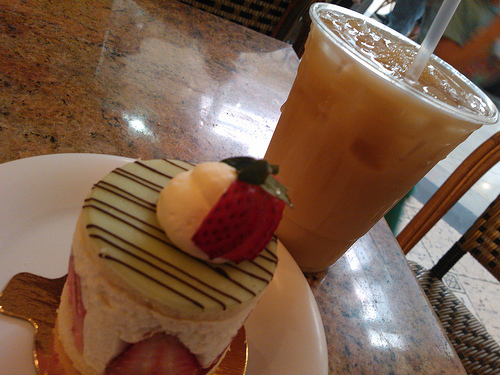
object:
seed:
[209, 226, 217, 237]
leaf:
[260, 171, 294, 208]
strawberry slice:
[194, 178, 279, 262]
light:
[199, 94, 276, 159]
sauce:
[68, 244, 86, 353]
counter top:
[0, 0, 462, 375]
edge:
[306, 2, 499, 130]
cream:
[153, 159, 234, 261]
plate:
[0, 150, 327, 374]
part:
[157, 294, 197, 331]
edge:
[155, 303, 204, 324]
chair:
[395, 132, 499, 375]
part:
[426, 245, 466, 299]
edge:
[400, 272, 432, 331]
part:
[427, 230, 447, 260]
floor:
[382, 100, 500, 346]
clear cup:
[245, 3, 499, 272]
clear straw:
[395, 0, 463, 78]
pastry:
[51, 144, 286, 371]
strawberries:
[194, 157, 294, 265]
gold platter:
[0, 270, 246, 374]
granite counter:
[0, 0, 499, 375]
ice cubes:
[245, 3, 499, 275]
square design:
[445, 327, 465, 343]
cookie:
[54, 156, 295, 375]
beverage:
[257, 0, 499, 276]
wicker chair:
[392, 129, 499, 374]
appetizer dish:
[48, 153, 293, 375]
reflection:
[111, 3, 301, 161]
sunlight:
[103, 19, 303, 163]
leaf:
[221, 155, 268, 188]